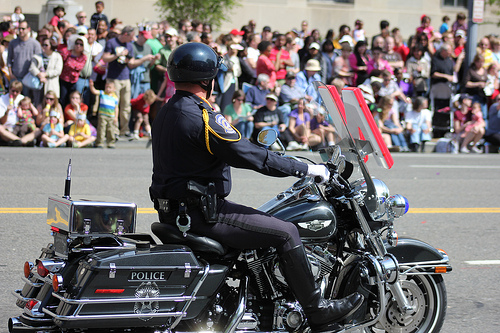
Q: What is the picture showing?
A: It is showing a street.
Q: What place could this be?
A: It is a street.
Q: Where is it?
A: This is at the street.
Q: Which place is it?
A: It is a street.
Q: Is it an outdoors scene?
A: Yes, it is outdoors.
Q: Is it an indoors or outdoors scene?
A: It is outdoors.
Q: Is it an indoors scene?
A: No, it is outdoors.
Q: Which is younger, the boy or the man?
A: The boy is younger than the man.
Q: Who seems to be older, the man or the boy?
A: The man is older than the boy.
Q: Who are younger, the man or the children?
A: The children are younger than the man.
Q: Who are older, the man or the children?
A: The man are older than the children.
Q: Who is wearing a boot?
A: The officer is wearing a boot.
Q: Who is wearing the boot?
A: The officer is wearing a boot.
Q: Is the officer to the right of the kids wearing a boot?
A: Yes, the officer is wearing a boot.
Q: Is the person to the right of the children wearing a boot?
A: Yes, the officer is wearing a boot.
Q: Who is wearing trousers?
A: The officer is wearing trousers.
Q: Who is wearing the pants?
A: The officer is wearing trousers.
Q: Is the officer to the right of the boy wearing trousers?
A: Yes, the officer is wearing trousers.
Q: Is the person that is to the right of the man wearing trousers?
A: Yes, the officer is wearing trousers.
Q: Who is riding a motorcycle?
A: The officer is riding a motorcycle.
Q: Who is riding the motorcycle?
A: The officer is riding a motorcycle.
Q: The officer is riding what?
A: The officer is riding a motorcycle.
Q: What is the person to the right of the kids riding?
A: The officer is riding a motorcycle.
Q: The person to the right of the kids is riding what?
A: The officer is riding a motorcycle.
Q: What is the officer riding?
A: The officer is riding a motorcycle.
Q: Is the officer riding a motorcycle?
A: Yes, the officer is riding a motorcycle.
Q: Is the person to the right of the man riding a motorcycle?
A: Yes, the officer is riding a motorcycle.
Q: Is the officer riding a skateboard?
A: No, the officer is riding a motorcycle.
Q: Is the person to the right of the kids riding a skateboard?
A: No, the officer is riding a motorcycle.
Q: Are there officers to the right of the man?
A: Yes, there is an officer to the right of the man.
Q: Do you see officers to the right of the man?
A: Yes, there is an officer to the right of the man.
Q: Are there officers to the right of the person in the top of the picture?
A: Yes, there is an officer to the right of the man.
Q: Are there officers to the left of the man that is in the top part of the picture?
A: No, the officer is to the right of the man.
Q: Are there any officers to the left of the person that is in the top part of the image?
A: No, the officer is to the right of the man.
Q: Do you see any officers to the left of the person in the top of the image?
A: No, the officer is to the right of the man.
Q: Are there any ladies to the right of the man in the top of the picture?
A: No, there is an officer to the right of the man.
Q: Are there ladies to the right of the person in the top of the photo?
A: No, there is an officer to the right of the man.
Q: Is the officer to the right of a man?
A: Yes, the officer is to the right of a man.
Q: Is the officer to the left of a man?
A: No, the officer is to the right of a man.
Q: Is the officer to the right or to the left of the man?
A: The officer is to the right of the man.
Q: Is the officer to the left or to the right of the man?
A: The officer is to the right of the man.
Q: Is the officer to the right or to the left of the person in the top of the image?
A: The officer is to the right of the man.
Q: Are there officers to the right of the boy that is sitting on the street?
A: Yes, there is an officer to the right of the boy.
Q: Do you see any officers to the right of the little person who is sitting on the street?
A: Yes, there is an officer to the right of the boy.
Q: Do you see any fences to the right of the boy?
A: No, there is an officer to the right of the boy.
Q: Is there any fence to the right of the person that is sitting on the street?
A: No, there is an officer to the right of the boy.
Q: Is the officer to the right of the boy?
A: Yes, the officer is to the right of the boy.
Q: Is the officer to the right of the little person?
A: Yes, the officer is to the right of the boy.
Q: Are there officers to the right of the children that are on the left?
A: Yes, there is an officer to the right of the children.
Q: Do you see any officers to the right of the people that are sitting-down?
A: Yes, there is an officer to the right of the children.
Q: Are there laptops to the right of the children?
A: No, there is an officer to the right of the children.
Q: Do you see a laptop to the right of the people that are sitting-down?
A: No, there is an officer to the right of the children.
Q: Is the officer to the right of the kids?
A: Yes, the officer is to the right of the kids.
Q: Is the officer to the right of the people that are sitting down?
A: Yes, the officer is to the right of the kids.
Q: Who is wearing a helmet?
A: The officer is wearing a helmet.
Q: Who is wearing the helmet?
A: The officer is wearing a helmet.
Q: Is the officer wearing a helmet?
A: Yes, the officer is wearing a helmet.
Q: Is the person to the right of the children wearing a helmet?
A: Yes, the officer is wearing a helmet.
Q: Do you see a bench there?
A: No, there are no benches.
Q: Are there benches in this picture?
A: No, there are no benches.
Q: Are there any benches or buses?
A: No, there are no benches or buses.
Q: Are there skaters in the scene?
A: No, there are no skaters.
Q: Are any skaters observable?
A: No, there are no skaters.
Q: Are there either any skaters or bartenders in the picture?
A: No, there are no skaters or bartenders.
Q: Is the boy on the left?
A: Yes, the boy is on the left of the image.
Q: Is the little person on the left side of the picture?
A: Yes, the boy is on the left of the image.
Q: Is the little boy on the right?
A: No, the boy is on the left of the image.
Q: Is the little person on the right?
A: No, the boy is on the left of the image.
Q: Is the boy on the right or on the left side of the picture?
A: The boy is on the left of the image.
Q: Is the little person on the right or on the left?
A: The boy is on the left of the image.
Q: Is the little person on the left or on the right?
A: The boy is on the left of the image.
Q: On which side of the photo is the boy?
A: The boy is on the left of the image.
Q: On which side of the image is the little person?
A: The boy is on the left of the image.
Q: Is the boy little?
A: Yes, the boy is little.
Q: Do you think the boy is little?
A: Yes, the boy is little.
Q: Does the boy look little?
A: Yes, the boy is little.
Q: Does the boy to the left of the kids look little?
A: Yes, the boy is little.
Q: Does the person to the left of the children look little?
A: Yes, the boy is little.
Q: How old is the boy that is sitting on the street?
A: The boy is little.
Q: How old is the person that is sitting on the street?
A: The boy is little.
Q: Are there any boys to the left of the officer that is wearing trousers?
A: Yes, there is a boy to the left of the officer.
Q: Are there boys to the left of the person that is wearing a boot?
A: Yes, there is a boy to the left of the officer.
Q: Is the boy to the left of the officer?
A: Yes, the boy is to the left of the officer.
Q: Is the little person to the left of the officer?
A: Yes, the boy is to the left of the officer.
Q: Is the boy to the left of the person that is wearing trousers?
A: Yes, the boy is to the left of the officer.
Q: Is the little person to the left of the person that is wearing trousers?
A: Yes, the boy is to the left of the officer.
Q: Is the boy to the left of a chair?
A: No, the boy is to the left of the officer.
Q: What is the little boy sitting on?
A: The boy is sitting on the street.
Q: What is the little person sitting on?
A: The boy is sitting on the street.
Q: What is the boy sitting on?
A: The boy is sitting on the street.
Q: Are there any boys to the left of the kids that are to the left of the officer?
A: Yes, there is a boy to the left of the kids.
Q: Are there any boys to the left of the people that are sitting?
A: Yes, there is a boy to the left of the kids.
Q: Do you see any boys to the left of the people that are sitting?
A: Yes, there is a boy to the left of the kids.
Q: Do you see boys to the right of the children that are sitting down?
A: No, the boy is to the left of the kids.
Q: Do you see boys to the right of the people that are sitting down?
A: No, the boy is to the left of the kids.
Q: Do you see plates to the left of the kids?
A: No, there is a boy to the left of the kids.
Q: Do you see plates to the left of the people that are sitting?
A: No, there is a boy to the left of the kids.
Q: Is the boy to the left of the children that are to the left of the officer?
A: Yes, the boy is to the left of the children.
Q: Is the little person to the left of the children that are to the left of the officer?
A: Yes, the boy is to the left of the children.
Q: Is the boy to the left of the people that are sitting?
A: Yes, the boy is to the left of the children.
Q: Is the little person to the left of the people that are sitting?
A: Yes, the boy is to the left of the children.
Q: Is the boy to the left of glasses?
A: No, the boy is to the left of the children.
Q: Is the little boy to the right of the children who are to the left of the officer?
A: No, the boy is to the left of the children.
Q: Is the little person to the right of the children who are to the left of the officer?
A: No, the boy is to the left of the children.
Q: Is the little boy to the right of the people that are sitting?
A: No, the boy is to the left of the children.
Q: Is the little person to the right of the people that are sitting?
A: No, the boy is to the left of the children.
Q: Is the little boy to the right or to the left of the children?
A: The boy is to the left of the children.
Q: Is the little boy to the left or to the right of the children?
A: The boy is to the left of the children.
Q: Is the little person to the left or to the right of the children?
A: The boy is to the left of the children.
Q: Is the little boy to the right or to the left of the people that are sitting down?
A: The boy is to the left of the children.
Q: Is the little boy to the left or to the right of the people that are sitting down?
A: The boy is to the left of the children.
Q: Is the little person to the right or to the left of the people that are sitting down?
A: The boy is to the left of the children.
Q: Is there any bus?
A: No, there are no buses.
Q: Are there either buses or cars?
A: No, there are no buses or cars.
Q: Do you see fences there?
A: No, there are no fences.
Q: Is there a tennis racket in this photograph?
A: No, there are no rackets.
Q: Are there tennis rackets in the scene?
A: No, there are no tennis rackets.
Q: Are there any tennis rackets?
A: No, there are no tennis rackets.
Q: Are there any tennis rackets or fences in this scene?
A: No, there are no tennis rackets or fences.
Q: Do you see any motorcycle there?
A: Yes, there is a motorcycle.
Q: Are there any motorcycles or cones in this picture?
A: Yes, there is a motorcycle.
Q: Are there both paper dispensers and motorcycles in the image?
A: No, there is a motorcycle but no paper dispensers.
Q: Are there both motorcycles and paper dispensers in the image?
A: No, there is a motorcycle but no paper dispensers.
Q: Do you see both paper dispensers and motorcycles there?
A: No, there is a motorcycle but no paper dispensers.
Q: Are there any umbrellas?
A: No, there are no umbrellas.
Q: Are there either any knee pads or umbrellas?
A: No, there are no umbrellas or knee pads.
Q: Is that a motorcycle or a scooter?
A: That is a motorcycle.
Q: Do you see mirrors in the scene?
A: Yes, there is a mirror.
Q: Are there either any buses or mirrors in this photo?
A: Yes, there is a mirror.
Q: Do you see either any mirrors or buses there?
A: Yes, there is a mirror.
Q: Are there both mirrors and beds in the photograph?
A: No, there is a mirror but no beds.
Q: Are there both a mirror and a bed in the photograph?
A: No, there is a mirror but no beds.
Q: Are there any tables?
A: No, there are no tables.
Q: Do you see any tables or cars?
A: No, there are no tables or cars.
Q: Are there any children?
A: Yes, there are children.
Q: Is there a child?
A: Yes, there are children.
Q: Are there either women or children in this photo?
A: Yes, there are children.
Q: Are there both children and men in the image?
A: Yes, there are both children and a man.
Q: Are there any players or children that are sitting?
A: Yes, the children are sitting.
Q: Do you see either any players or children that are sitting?
A: Yes, the children are sitting.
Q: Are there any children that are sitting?
A: Yes, there are children that are sitting.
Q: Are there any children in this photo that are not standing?
A: Yes, there are children that are sitting.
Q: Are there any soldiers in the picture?
A: No, there are no soldiers.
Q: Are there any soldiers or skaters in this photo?
A: No, there are no soldiers or skaters.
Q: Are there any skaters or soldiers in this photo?
A: No, there are no soldiers or skaters.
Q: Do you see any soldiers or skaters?
A: No, there are no soldiers or skaters.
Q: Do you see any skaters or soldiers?
A: No, there are no soldiers or skaters.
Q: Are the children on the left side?
A: Yes, the children are on the left of the image.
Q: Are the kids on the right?
A: No, the kids are on the left of the image.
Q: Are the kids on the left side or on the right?
A: The kids are on the left of the image.